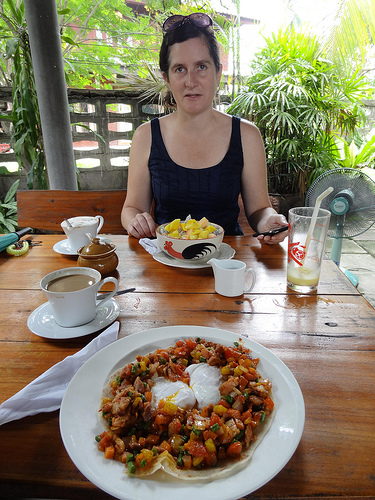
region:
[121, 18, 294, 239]
Woman sitting by a table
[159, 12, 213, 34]
Sunglasses on the woman's head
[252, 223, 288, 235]
Cellphone in the woman's left hand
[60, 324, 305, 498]
A plate of food on the table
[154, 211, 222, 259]
A bowl of food on the table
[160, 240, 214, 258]
Chicken picture on the bowl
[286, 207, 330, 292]
A glass on the table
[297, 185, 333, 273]
A straw in the glass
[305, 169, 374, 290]
Fan on the ground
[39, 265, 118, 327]
Coffee on the table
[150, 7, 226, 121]
the head of a woman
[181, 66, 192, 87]
the nose of a woman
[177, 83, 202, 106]
the mouth of a woman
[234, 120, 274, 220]
the arm of a woman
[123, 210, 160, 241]
the hand of a woman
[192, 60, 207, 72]
the eye of a woman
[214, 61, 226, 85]
the ear of a woman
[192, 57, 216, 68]
the eyebrow of a woman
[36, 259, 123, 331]
a white coffee cup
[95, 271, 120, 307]
the handle of the coffee cup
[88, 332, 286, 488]
food on a white plate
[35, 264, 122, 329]
cup on a saucer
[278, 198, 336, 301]
glass on a table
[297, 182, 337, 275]
straw in a glass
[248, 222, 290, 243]
phone in a persons hand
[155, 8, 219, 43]
glasses on a persons head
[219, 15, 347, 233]
green plants behind a person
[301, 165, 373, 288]
fan on the ground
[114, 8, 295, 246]
person with a black shirt sitting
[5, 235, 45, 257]
keys on a table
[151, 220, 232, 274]
bowl with rooster on side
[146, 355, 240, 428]
two dollops of sourcream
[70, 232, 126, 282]
brown lidded sugar bowl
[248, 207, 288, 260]
cell phone in woman's hand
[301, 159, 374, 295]
blue fan on the floor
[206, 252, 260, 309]
white cream pitcher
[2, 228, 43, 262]
set of keys on the table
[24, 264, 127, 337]
cup of coffee without foam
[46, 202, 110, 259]
cup of coffee with foam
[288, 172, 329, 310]
glass with straw in it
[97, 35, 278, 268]
Woman eating breakfast outdoors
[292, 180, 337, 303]
Mostly empty glass of juice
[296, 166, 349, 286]
White bendy style straw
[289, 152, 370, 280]
Light green rotating fan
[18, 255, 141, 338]
Cup of coffee with saucer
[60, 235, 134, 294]
Small brown sugar bowl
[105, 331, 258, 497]
Eggs with hash of potatoes and meat on tortilla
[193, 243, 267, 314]
Small white cream pitcher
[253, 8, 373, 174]
Bright green tropical plants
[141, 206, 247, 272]
Bowl of fruit with rooster on it